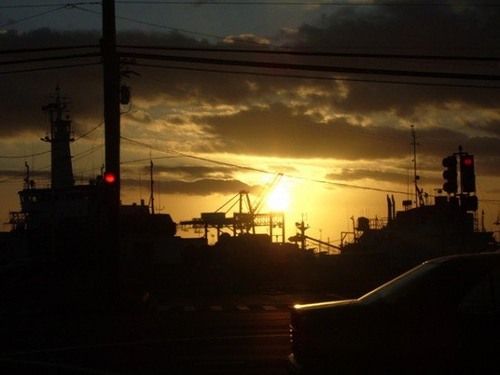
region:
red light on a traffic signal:
[101, 166, 122, 190]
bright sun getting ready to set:
[257, 178, 303, 223]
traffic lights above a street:
[436, 141, 486, 202]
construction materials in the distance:
[177, 171, 305, 246]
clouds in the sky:
[201, 109, 416, 164]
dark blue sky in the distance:
[162, 5, 295, 25]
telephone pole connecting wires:
[92, 2, 141, 219]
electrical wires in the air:
[136, 36, 481, 107]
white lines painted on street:
[181, 298, 272, 318]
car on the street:
[267, 239, 494, 373]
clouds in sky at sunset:
[134, 35, 214, 97]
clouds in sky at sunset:
[172, 158, 226, 198]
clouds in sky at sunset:
[9, 47, 51, 119]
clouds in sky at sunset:
[139, 41, 174, 93]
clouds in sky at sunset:
[204, 47, 268, 106]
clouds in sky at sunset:
[302, 25, 362, 117]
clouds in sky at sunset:
[323, 102, 385, 152]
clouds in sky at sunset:
[386, 19, 484, 134]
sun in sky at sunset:
[263, 176, 302, 216]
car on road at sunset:
[287, 251, 472, 359]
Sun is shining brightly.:
[235, 169, 306, 224]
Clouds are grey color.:
[166, 48, 353, 88]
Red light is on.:
[93, 165, 116, 190]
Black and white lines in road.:
[182, 287, 305, 323]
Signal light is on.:
[427, 146, 486, 224]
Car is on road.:
[275, 252, 499, 368]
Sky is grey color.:
[134, 5, 290, 26]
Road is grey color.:
[213, 311, 290, 356]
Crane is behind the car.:
[189, 164, 292, 244]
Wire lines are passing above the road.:
[31, 38, 493, 98]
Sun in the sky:
[261, 176, 298, 218]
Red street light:
[453, 148, 481, 193]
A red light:
[101, 166, 120, 183]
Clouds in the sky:
[153, 26, 457, 153]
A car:
[285, 252, 487, 353]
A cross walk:
[174, 295, 262, 317]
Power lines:
[135, 40, 330, 80]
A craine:
[258, 175, 285, 201]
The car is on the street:
[182, 322, 247, 350]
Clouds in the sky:
[191, 41, 385, 154]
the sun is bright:
[202, 121, 387, 371]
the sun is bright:
[231, 91, 336, 325]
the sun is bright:
[235, 160, 290, 355]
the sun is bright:
[255, 175, 358, 358]